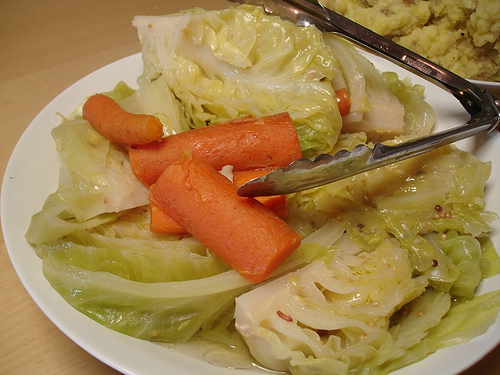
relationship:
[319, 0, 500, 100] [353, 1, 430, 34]
bowl of cauliflower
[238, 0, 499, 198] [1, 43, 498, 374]
tong laying on plate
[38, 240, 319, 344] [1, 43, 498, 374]
cabbage on top of plate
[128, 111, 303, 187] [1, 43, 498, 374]
carrot on plate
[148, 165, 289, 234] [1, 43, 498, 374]
carrot on plate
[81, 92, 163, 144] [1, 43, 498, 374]
carrot on plate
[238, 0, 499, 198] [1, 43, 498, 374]
tong on top of plate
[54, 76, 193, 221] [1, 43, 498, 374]
cabbage on plate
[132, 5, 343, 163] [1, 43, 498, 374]
cabbage on plate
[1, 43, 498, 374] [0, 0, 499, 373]
plate on table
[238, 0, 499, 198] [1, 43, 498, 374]
tong rests on plate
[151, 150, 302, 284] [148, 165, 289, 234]
carrot on top of carrot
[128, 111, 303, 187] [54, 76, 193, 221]
carrot on top of cabbage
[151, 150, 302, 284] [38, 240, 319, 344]
carrot on cabbage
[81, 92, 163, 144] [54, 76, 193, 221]
carrot on cabbage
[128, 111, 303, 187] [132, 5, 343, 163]
carrot on top of cabbage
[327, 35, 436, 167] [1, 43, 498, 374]
cabbage on plate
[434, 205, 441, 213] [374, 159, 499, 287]
spice on cabbage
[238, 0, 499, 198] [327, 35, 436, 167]
tong on cabbage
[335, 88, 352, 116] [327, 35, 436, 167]
carrot on cabbage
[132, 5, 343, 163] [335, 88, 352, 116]
cabbage on carrot